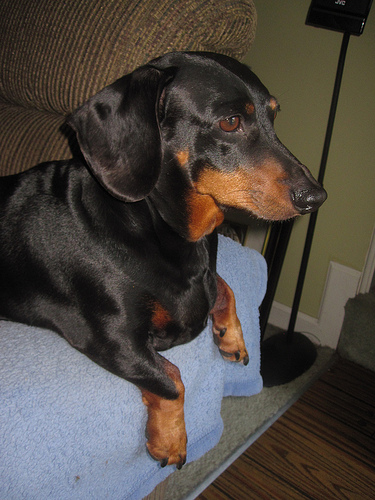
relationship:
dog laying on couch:
[0, 49, 328, 469] [0, 0, 268, 499]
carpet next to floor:
[136, 324, 335, 500] [177, 356, 373, 497]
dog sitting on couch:
[0, 49, 328, 469] [0, 0, 268, 499]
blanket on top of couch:
[1, 233, 268, 498] [0, 0, 268, 499]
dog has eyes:
[0, 49, 328, 469] [216, 106, 278, 133]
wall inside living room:
[239, 0, 374, 350] [0, 1, 373, 498]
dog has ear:
[0, 49, 328, 469] [61, 61, 172, 203]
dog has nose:
[0, 49, 328, 469] [293, 180, 327, 218]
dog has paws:
[0, 49, 328, 469] [142, 318, 251, 472]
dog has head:
[0, 49, 328, 469] [66, 49, 329, 238]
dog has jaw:
[0, 49, 328, 469] [218, 207, 288, 230]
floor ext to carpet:
[177, 356, 373, 497] [136, 324, 335, 500]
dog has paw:
[0, 49, 328, 469] [209, 314, 249, 368]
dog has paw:
[0, 49, 328, 469] [144, 408, 189, 470]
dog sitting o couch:
[0, 49, 328, 469] [0, 0, 268, 499]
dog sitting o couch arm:
[0, 49, 328, 469] [1, 218, 239, 461]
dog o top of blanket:
[0, 49, 328, 469] [1, 233, 268, 498]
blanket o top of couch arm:
[1, 233, 268, 498] [1, 218, 239, 461]